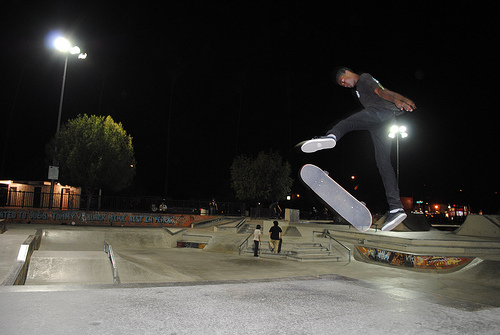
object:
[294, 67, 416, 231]
skateboarder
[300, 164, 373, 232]
skateboard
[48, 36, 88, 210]
street light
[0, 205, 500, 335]
park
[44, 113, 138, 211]
tree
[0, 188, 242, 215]
railing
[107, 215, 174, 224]
graffiti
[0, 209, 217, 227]
wall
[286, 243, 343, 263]
steps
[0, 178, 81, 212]
buildings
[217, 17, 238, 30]
sky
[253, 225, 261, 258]
people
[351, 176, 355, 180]
traffic signals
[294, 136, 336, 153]
shoe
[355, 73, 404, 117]
shirt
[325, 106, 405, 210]
pants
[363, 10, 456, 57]
air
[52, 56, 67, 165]
pole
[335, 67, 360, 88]
head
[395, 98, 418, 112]
hand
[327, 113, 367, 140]
leg